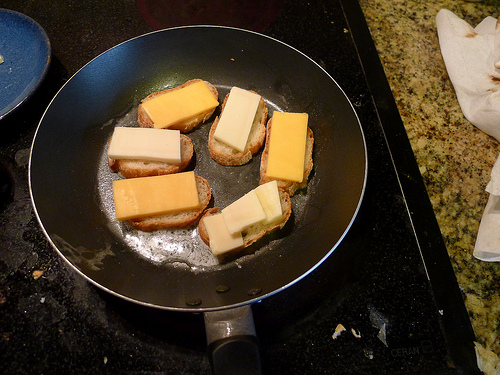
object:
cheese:
[261, 110, 325, 182]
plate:
[0, 9, 52, 121]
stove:
[0, 0, 479, 375]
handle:
[201, 310, 256, 365]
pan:
[25, 22, 369, 375]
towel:
[437, 10, 499, 264]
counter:
[358, 0, 500, 374]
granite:
[469, 267, 496, 347]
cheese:
[103, 124, 186, 164]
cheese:
[109, 173, 206, 219]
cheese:
[140, 81, 219, 130]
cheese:
[203, 181, 281, 257]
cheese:
[210, 84, 261, 152]